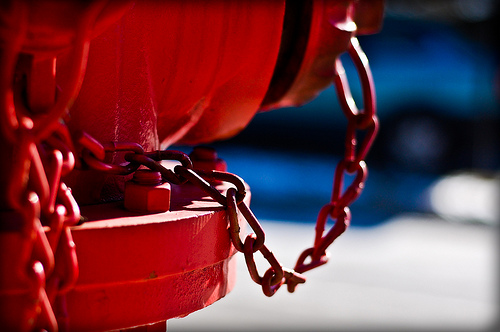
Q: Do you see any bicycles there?
A: No, there are no bicycles.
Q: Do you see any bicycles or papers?
A: No, there are no bicycles or papers.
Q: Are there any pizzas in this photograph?
A: No, there are no pizzas.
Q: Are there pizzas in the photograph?
A: No, there are no pizzas.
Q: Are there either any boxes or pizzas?
A: No, there are no pizzas or boxes.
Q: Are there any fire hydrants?
A: Yes, there is a fire hydrant.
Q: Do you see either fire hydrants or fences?
A: Yes, there is a fire hydrant.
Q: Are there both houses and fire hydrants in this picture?
A: No, there is a fire hydrant but no houses.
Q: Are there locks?
A: No, there are no locks.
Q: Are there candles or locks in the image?
A: No, there are no locks or candles.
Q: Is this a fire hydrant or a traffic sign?
A: This is a fire hydrant.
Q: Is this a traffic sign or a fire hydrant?
A: This is a fire hydrant.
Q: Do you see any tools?
A: No, there are no tools.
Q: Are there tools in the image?
A: No, there are no tools.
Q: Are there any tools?
A: No, there are no tools.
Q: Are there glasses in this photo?
A: No, there are no glasses.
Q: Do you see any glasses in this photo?
A: No, there are no glasses.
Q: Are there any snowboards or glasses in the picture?
A: No, there are no glasses or snowboards.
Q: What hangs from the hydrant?
A: The chain hangs from the hydrant.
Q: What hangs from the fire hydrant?
A: The chain hangs from the hydrant.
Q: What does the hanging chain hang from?
A: The chain hangs from the fire hydrant.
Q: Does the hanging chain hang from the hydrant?
A: Yes, the chain hangs from the hydrant.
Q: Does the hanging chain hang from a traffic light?
A: No, the chain hangs from the hydrant.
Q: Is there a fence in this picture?
A: No, there are no fences.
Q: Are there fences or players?
A: No, there are no fences or players.